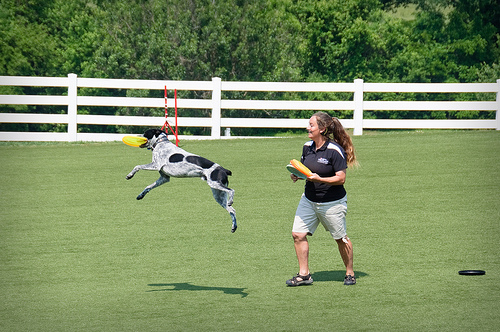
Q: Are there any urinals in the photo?
A: No, there are no urinals.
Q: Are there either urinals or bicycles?
A: No, there are no urinals or bicycles.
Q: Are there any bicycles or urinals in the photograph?
A: No, there are no urinals or bicycles.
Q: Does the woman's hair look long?
A: Yes, the hair is long.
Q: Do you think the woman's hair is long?
A: Yes, the hair is long.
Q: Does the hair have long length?
A: Yes, the hair is long.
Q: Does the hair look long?
A: Yes, the hair is long.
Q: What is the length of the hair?
A: The hair is long.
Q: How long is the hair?
A: The hair is long.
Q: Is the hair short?
A: No, the hair is long.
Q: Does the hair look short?
A: No, the hair is long.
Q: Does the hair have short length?
A: No, the hair is long.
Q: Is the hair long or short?
A: The hair is long.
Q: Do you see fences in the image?
A: Yes, there is a fence.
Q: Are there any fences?
A: Yes, there is a fence.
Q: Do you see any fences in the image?
A: Yes, there is a fence.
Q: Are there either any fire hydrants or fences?
A: Yes, there is a fence.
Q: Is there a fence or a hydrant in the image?
A: Yes, there is a fence.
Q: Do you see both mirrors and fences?
A: No, there is a fence but no mirrors.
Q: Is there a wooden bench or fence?
A: Yes, there is a wood fence.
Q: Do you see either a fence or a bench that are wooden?
A: Yes, the fence is wooden.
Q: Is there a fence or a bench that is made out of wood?
A: Yes, the fence is made of wood.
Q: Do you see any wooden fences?
A: Yes, there is a wood fence.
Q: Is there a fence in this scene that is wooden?
A: Yes, there is a fence that is wooden.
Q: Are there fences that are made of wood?
A: Yes, there is a fence that is made of wood.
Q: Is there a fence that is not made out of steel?
A: Yes, there is a fence that is made of wood.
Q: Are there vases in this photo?
A: No, there are no vases.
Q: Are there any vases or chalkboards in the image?
A: No, there are no vases or chalkboards.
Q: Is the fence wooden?
A: Yes, the fence is wooden.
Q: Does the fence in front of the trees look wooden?
A: Yes, the fence is wooden.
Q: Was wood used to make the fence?
A: Yes, the fence is made of wood.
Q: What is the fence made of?
A: The fence is made of wood.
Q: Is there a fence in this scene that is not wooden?
A: No, there is a fence but it is wooden.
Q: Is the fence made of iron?
A: No, the fence is made of wood.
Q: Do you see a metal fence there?
A: No, there is a fence but it is made of wood.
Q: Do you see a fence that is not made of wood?
A: No, there is a fence but it is made of wood.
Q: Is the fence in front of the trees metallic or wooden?
A: The fence is wooden.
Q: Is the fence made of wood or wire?
A: The fence is made of wood.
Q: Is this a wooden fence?
A: Yes, this is a wooden fence.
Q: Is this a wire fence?
A: No, this is a wooden fence.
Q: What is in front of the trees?
A: The fence is in front of the trees.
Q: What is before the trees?
A: The fence is in front of the trees.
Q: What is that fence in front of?
A: The fence is in front of the trees.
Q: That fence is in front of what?
A: The fence is in front of the trees.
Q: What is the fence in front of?
A: The fence is in front of the trees.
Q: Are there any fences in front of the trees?
A: Yes, there is a fence in front of the trees.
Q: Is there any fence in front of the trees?
A: Yes, there is a fence in front of the trees.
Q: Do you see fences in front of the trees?
A: Yes, there is a fence in front of the trees.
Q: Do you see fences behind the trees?
A: No, the fence is in front of the trees.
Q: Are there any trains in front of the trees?
A: No, there is a fence in front of the trees.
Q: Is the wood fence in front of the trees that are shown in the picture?
A: Yes, the fence is in front of the trees.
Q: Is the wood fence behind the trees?
A: No, the fence is in front of the trees.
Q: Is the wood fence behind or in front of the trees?
A: The fence is in front of the trees.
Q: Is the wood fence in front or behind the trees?
A: The fence is in front of the trees.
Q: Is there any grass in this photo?
A: Yes, there is grass.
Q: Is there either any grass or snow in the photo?
A: Yes, there is grass.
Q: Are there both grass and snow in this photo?
A: No, there is grass but no snow.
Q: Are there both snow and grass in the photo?
A: No, there is grass but no snow.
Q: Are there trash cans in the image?
A: No, there are no trash cans.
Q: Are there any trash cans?
A: No, there are no trash cans.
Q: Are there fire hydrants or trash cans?
A: No, there are no trash cans or fire hydrants.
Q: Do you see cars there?
A: No, there are no cars.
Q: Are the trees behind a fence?
A: Yes, the trees are behind a fence.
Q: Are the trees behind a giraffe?
A: No, the trees are behind a fence.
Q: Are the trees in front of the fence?
A: No, the trees are behind the fence.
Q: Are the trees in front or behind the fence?
A: The trees are behind the fence.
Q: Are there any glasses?
A: No, there are no glasses.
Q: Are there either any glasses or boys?
A: No, there are no glasses or boys.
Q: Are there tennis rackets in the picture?
A: No, there are no tennis rackets.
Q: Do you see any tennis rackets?
A: No, there are no tennis rackets.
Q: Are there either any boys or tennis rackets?
A: No, there are no tennis rackets or boys.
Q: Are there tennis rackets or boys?
A: No, there are no tennis rackets or boys.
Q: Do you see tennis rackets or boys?
A: No, there are no tennis rackets or boys.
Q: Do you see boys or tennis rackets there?
A: No, there are no tennis rackets or boys.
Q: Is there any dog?
A: Yes, there is a dog.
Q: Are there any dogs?
A: Yes, there is a dog.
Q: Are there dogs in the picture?
A: Yes, there is a dog.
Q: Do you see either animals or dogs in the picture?
A: Yes, there is a dog.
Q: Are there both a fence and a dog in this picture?
A: Yes, there are both a dog and a fence.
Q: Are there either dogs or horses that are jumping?
A: Yes, the dog is jumping.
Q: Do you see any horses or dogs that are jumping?
A: Yes, the dog is jumping.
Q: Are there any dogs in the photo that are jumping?
A: Yes, there is a dog that is jumping.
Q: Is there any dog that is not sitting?
A: Yes, there is a dog that is jumping.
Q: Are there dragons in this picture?
A: No, there are no dragons.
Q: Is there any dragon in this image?
A: No, there are no dragons.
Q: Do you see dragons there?
A: No, there are no dragons.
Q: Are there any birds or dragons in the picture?
A: No, there are no dragons or birds.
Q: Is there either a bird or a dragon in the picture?
A: No, there are no dragons or birds.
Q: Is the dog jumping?
A: Yes, the dog is jumping.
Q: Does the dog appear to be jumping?
A: Yes, the dog is jumping.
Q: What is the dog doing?
A: The dog is jumping.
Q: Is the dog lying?
A: No, the dog is jumping.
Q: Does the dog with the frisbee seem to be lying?
A: No, the dog is jumping.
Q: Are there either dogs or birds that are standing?
A: No, there is a dog but it is jumping.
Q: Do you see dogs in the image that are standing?
A: No, there is a dog but it is jumping.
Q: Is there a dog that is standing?
A: No, there is a dog but it is jumping.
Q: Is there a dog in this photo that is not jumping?
A: No, there is a dog but it is jumping.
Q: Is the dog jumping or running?
A: The dog is jumping.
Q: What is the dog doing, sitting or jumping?
A: The dog is jumping.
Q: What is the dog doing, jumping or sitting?
A: The dog is jumping.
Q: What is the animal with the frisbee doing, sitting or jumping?
A: The dog is jumping.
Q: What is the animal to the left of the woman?
A: The animal is a dog.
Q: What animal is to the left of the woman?
A: The animal is a dog.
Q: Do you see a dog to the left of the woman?
A: Yes, there is a dog to the left of the woman.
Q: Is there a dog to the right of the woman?
A: No, the dog is to the left of the woman.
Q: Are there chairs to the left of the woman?
A: No, there is a dog to the left of the woman.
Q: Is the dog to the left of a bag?
A: No, the dog is to the left of a woman.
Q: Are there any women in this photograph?
A: Yes, there is a woman.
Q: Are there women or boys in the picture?
A: Yes, there is a woman.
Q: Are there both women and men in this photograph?
A: No, there is a woman but no men.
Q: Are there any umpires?
A: No, there are no umpires.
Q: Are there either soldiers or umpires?
A: No, there are no umpires or soldiers.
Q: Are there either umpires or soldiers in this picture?
A: No, there are no umpires or soldiers.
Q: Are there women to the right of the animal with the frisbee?
A: Yes, there is a woman to the right of the dog.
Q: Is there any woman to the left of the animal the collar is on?
A: No, the woman is to the right of the dog.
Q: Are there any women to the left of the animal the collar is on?
A: No, the woman is to the right of the dog.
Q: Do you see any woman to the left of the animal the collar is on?
A: No, the woman is to the right of the dog.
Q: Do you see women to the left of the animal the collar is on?
A: No, the woman is to the right of the dog.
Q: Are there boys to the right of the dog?
A: No, there is a woman to the right of the dog.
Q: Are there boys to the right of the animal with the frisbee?
A: No, there is a woman to the right of the dog.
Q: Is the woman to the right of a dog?
A: Yes, the woman is to the right of a dog.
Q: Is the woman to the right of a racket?
A: No, the woman is to the right of a dog.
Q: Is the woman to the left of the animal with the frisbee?
A: No, the woman is to the right of the dog.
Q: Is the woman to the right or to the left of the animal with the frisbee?
A: The woman is to the right of the dog.